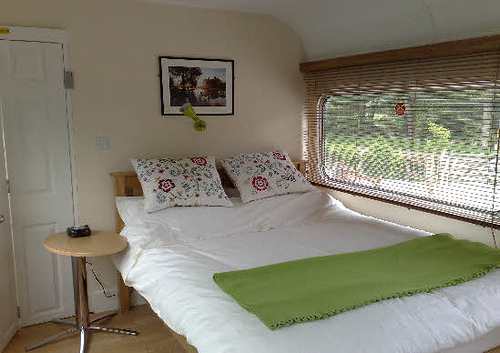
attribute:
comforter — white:
[135, 197, 468, 341]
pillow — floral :
[127, 152, 232, 212]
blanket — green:
[196, 231, 498, 335]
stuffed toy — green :
[177, 101, 209, 131]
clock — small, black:
[64, 224, 92, 238]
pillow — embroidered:
[137, 149, 227, 205]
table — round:
[35, 219, 130, 351]